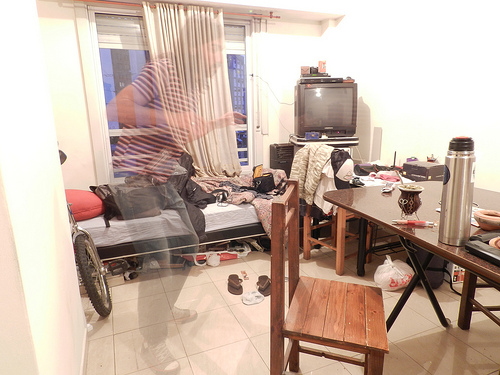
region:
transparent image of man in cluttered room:
[2, 3, 499, 373]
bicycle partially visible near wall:
[13, 125, 120, 322]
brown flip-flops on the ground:
[216, 258, 271, 307]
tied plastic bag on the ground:
[366, 248, 418, 300]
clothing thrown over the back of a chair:
[281, 140, 364, 270]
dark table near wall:
[335, 119, 499, 339]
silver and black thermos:
[434, 127, 486, 261]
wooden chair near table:
[261, 175, 431, 373]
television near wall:
[259, 35, 391, 164]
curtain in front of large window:
[79, 0, 261, 181]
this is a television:
[298, 83, 358, 138]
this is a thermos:
[443, 139, 473, 246]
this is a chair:
[268, 181, 310, 373]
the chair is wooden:
[306, 287, 371, 323]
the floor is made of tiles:
[207, 297, 239, 365]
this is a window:
[101, 17, 129, 83]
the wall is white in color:
[396, 16, 477, 113]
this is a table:
[344, 192, 386, 207]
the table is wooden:
[352, 189, 377, 212]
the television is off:
[302, 82, 358, 134]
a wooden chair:
[256, 169, 393, 373]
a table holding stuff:
[323, 175, 497, 332]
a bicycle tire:
[76, 231, 120, 318]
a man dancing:
[111, 10, 241, 371]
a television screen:
[294, 75, 362, 136]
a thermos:
[431, 132, 475, 244]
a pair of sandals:
[218, 265, 276, 307]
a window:
[96, 34, 249, 193]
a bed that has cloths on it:
[68, 174, 285, 245]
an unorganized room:
[4, 0, 494, 370]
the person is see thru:
[106, 7, 226, 373]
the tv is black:
[277, 65, 371, 143]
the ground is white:
[190, 310, 262, 373]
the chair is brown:
[257, 173, 380, 370]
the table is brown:
[320, 161, 497, 317]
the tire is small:
[65, 217, 140, 332]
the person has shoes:
[127, 293, 210, 372]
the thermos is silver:
[430, 129, 483, 261]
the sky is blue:
[102, 51, 117, 91]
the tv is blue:
[287, 69, 369, 142]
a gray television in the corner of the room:
[293, 80, 358, 140]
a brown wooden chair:
[268, 175, 392, 373]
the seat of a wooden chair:
[282, 274, 389, 356]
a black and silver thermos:
[434, 135, 476, 248]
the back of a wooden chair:
[263, 177, 303, 329]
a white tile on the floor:
[111, 315, 193, 373]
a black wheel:
[69, 230, 118, 320]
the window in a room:
[85, 4, 258, 183]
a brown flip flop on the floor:
[225, 272, 247, 299]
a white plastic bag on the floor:
[371, 250, 416, 291]